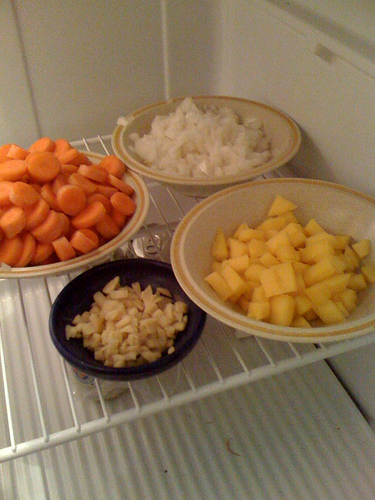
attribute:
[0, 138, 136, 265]
carrots — sliced, orange, chopped, cut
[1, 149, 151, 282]
bowl — white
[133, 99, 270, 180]
onions — chopped, white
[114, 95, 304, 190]
bowl — white, gold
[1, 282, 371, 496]
bottom shelf — plastic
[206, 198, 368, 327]
pineapples — yellow, chopped, cut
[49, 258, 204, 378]
bowl — blue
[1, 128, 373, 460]
shelf — metal, white, wire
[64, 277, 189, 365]
nuts — chopped, minced